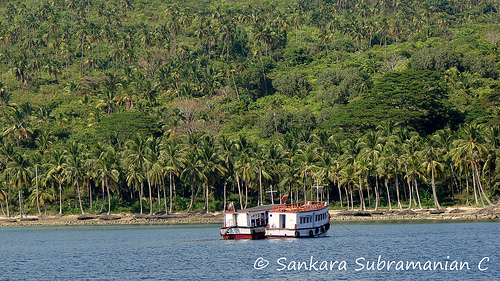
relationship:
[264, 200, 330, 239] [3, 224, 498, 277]
boat on water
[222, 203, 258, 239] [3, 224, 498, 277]
boat in water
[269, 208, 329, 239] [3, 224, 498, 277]
boat in water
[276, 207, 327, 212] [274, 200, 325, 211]
railings on top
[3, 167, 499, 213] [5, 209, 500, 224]
trees on shore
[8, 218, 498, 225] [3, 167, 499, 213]
beach covered in trees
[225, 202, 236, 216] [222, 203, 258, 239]
flags on boat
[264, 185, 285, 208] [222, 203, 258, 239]
cross on boat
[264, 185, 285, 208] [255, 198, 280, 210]
cross in front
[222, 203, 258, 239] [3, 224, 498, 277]
boat on water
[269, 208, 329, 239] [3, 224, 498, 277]
boat on water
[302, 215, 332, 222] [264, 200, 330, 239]
windows on boat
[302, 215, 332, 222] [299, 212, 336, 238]
windows on side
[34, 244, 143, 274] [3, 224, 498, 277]
ripple on water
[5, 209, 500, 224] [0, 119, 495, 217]
sand on beach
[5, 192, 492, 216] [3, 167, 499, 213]
trunks of trees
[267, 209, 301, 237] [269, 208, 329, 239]
back of boat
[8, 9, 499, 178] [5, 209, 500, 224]
hill by shore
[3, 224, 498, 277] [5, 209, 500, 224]
water by shore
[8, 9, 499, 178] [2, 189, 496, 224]
jungle on shore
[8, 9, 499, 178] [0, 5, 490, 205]
trees are on hill